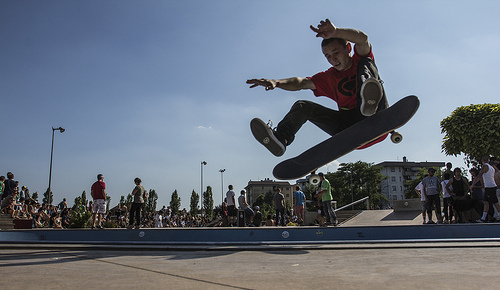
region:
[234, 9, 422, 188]
young man doing trick on skateboard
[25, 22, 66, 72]
white clouds in blue sky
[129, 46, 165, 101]
white clouds in blue sky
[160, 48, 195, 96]
white clouds in blue sky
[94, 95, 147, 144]
white clouds in blue sky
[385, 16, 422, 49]
white clouds in blue sky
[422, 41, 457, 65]
white clouds in blue sky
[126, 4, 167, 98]
white clouds in blue sky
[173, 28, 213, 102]
white clouds in blue sky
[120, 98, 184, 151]
white clouds in blue sky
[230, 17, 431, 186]
skateboarder in the air doing a trick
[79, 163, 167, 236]
people with their backs to the skateboarder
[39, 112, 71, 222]
street light behind the skate park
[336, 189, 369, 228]
railing at the skate park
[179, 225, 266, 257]
low wall of the skate park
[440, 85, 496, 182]
tree behind the skate park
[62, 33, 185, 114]
blue grey sky above the people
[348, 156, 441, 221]
building behind the skate park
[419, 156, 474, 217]
people watching the skateboarder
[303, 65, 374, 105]
red t shirt of the skateboarder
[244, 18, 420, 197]
a boy and a skateboard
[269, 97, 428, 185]
a black skateboard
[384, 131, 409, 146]
wheel on a skate board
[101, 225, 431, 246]
a rim around the concrete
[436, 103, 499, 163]
a green leafy tree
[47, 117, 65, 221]
a light on a pole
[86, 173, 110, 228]
a man in red and white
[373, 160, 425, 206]
a white house in the distance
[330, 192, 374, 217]
a metal rail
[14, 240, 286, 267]
a shadow on the concerte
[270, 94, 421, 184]
A skateboard flipped up in the air.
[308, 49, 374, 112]
A red short sleeve shirt with a black symbol.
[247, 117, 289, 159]
A tennis shoe.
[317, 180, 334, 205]
A short sleeve green shirt.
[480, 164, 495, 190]
A white tank top.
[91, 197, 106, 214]
Knee length white shorts.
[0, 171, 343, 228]
A large group of people.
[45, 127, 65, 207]
A tall light pole.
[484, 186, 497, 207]
A pair of dark shorts.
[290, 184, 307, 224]
A person in a blue shirt.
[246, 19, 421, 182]
Skateboarder doing a trick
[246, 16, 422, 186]
White skateboarder doing a trick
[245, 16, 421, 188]
Skateboarder wearing a red t-shirt doing a trick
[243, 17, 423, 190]
Skateboarder wearing a red t-shirt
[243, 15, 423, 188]
Skateboarder in black jeans doing a trick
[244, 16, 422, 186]
Skateboarder wearing black jeans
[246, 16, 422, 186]
Skateboarder wearing a red shirt and black jeans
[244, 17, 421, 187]
Skateboarder wearing a red shirt and black jeans doing a trick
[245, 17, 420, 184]
Man on a skateboard doing a trick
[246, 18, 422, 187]
Guy doing a trick on a skateboard